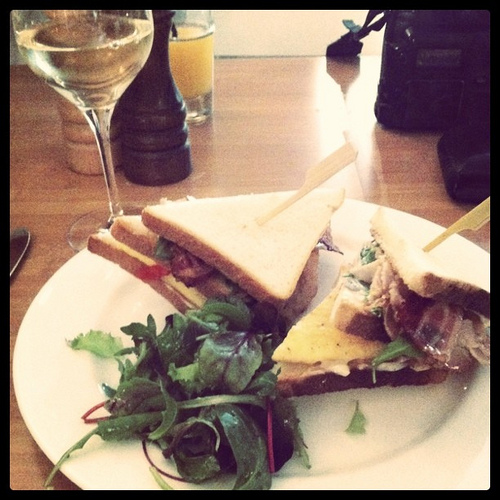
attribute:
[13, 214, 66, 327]
knife — silver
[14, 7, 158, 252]
salt mill — tall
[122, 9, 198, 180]
pepper mill — tall , black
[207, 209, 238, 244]
bread — brown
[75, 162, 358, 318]
bread — white, triangular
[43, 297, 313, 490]
salad — green, small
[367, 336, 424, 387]
leaf — green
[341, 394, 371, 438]
leaf — green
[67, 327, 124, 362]
leaf — green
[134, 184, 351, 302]
bread — brown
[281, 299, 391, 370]
cheese — white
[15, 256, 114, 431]
dinner plate — white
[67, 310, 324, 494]
vegetables — raw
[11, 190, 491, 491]
plate — white and circular, white, round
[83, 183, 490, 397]
sandwich — sliced, cut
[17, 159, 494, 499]
plate — closed